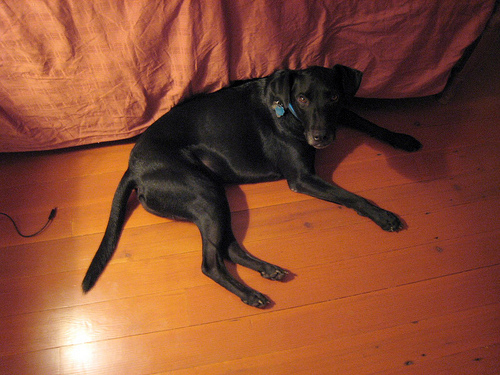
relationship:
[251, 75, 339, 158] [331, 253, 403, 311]
dog on floor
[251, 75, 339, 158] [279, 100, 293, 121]
dog wearing collar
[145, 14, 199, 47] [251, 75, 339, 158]
bed behind dog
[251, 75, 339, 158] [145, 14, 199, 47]
dog on bed